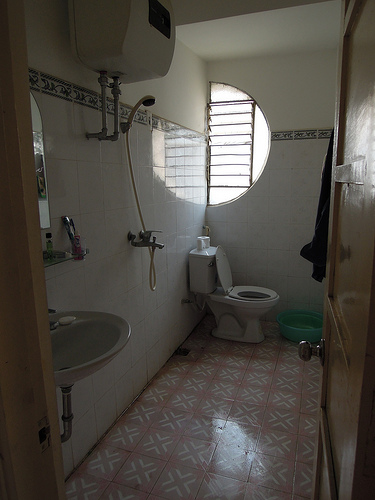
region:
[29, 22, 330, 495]
a full sized bathroom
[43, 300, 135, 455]
an oval sink attached to the wall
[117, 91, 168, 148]
a detachable shower head attached to the wall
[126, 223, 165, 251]
The shower faucet attached to the wall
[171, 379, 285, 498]
pink and white patterened flooring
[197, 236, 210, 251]
roll of toilet paper on top of the toilet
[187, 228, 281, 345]
standard size white toilet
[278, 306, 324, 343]
a green bowl on the floor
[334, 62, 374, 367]
brown wooden door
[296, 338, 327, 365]
silver door knob on bathroom door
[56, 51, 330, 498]
This is a toilet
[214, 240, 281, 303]
This is a toilet seat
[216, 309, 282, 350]
Base of a toilet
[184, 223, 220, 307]
Water cistern of a toilet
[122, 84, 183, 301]
This is a water tab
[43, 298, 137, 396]
This is a water sink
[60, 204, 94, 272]
This is a shelf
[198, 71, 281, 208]
This is a window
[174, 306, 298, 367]
Base of a toilet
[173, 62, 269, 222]
half circle window with rack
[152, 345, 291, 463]
pink and white tiles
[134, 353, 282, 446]
the floor is tiled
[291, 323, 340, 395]
this is a door knob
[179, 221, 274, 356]
this is a toilet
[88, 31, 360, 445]
an open shower and tank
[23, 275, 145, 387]
this is a sink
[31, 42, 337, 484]
the room is a bathroom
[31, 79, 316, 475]
this bathroom is not american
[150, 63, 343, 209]
the reflection makes a circle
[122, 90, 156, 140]
Shower head on the wall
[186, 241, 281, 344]
White toilet in the corner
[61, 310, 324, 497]
Pink and white tiled floor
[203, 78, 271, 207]
Half of a circle window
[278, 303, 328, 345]
Green plastic tub on floor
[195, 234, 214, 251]
Roll of toilet paper on top of toilet tank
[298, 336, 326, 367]
Silver door know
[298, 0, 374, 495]
Opened wooden door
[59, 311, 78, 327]
Bar of soap on the sink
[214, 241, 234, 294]
Open toilet lid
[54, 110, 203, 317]
Bathroom wall with white tiles.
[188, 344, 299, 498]
Bathroom floor with x pattern.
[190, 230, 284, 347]
White toilet with seat down.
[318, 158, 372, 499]
Open wooden bathroom dor.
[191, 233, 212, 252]
Full roll of toilet paper on toilet.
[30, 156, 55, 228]
Bathroom mirror on wall.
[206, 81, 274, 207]
Window in shape of half circle.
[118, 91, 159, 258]
Shower head with faucet on wall.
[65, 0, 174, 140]
Large bathroom fan.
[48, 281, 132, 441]
Oval bathroom sink with bar of soap.